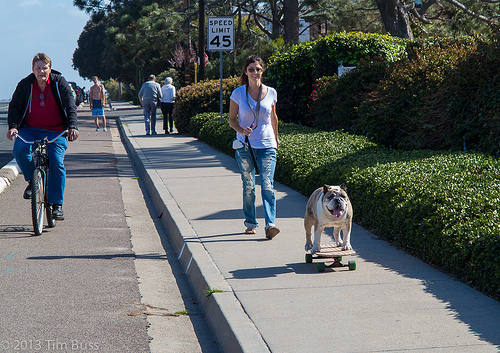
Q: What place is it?
A: It is a sidewalk.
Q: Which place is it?
A: It is a sidewalk.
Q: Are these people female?
A: No, they are both male and female.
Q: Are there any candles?
A: No, there are no candles.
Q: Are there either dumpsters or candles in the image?
A: No, there are no candles or dumpsters.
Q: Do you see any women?
A: Yes, there is a woman.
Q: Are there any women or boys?
A: Yes, there is a woman.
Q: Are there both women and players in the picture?
A: No, there is a woman but no players.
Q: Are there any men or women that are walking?
A: Yes, the woman is walking.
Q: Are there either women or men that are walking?
A: Yes, the woman is walking.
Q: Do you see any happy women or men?
A: Yes, there is a happy woman.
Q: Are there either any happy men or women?
A: Yes, there is a happy woman.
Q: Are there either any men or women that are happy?
A: Yes, the woman is happy.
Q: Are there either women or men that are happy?
A: Yes, the woman is happy.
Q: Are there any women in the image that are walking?
A: Yes, there is a woman that is walking.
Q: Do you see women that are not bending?
A: Yes, there is a woman that is walking .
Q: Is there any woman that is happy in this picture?
A: Yes, there is a happy woman.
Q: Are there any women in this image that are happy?
A: Yes, there is a happy woman.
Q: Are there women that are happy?
A: Yes, there is a woman that is happy.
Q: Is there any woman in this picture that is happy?
A: Yes, there is a woman that is happy.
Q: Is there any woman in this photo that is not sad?
A: Yes, there is a happy woman.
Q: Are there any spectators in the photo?
A: No, there are no spectators.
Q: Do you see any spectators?
A: No, there are no spectators.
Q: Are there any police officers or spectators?
A: No, there are no spectators or police officers.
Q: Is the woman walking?
A: Yes, the woman is walking.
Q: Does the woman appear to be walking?
A: Yes, the woman is walking.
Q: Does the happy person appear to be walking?
A: Yes, the woman is walking.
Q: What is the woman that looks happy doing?
A: The woman is walking.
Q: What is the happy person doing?
A: The woman is walking.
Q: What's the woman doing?
A: The woman is walking.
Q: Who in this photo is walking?
A: The woman is walking.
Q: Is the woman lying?
A: No, the woman is walking.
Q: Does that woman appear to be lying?
A: No, the woman is walking.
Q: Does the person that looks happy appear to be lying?
A: No, the woman is walking.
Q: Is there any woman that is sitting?
A: No, there is a woman but she is walking.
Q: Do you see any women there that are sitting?
A: No, there is a woman but she is walking.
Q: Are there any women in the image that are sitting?
A: No, there is a woman but she is walking.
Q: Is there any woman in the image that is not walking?
A: No, there is a woman but she is walking.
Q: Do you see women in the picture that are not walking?
A: No, there is a woman but she is walking.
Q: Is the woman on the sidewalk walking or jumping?
A: The woman is walking.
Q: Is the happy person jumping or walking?
A: The woman is walking.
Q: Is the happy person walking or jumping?
A: The woman is walking.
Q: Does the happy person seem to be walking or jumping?
A: The woman is walking.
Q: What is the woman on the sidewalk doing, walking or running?
A: The woman is walking.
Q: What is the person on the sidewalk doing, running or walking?
A: The woman is walking.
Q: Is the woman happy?
A: Yes, the woman is happy.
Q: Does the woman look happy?
A: Yes, the woman is happy.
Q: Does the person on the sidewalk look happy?
A: Yes, the woman is happy.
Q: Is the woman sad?
A: No, the woman is happy.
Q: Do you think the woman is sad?
A: No, the woman is happy.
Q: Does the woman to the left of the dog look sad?
A: No, the woman is happy.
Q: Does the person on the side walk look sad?
A: No, the woman is happy.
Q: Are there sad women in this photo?
A: No, there is a woman but she is happy.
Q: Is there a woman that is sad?
A: No, there is a woman but she is happy.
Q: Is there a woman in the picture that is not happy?
A: No, there is a woman but she is happy.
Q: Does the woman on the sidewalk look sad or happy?
A: The woman is happy.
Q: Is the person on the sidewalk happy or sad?
A: The woman is happy.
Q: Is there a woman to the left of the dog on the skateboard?
A: Yes, there is a woman to the left of the dog.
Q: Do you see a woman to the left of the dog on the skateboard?
A: Yes, there is a woman to the left of the dog.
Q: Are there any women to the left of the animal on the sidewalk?
A: Yes, there is a woman to the left of the dog.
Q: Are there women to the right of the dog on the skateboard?
A: No, the woman is to the left of the dog.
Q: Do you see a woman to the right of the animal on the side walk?
A: No, the woman is to the left of the dog.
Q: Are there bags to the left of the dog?
A: No, there is a woman to the left of the dog.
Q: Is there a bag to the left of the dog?
A: No, there is a woman to the left of the dog.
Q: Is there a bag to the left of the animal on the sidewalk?
A: No, there is a woman to the left of the dog.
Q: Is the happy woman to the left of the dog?
A: Yes, the woman is to the left of the dog.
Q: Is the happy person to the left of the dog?
A: Yes, the woman is to the left of the dog.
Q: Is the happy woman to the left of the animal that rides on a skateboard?
A: Yes, the woman is to the left of the dog.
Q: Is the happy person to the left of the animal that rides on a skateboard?
A: Yes, the woman is to the left of the dog.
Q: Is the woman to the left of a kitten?
A: No, the woman is to the left of the dog.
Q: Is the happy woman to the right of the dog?
A: No, the woman is to the left of the dog.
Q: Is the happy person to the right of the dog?
A: No, the woman is to the left of the dog.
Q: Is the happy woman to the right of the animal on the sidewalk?
A: No, the woman is to the left of the dog.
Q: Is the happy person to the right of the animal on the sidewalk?
A: No, the woman is to the left of the dog.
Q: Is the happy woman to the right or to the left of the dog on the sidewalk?
A: The woman is to the left of the dog.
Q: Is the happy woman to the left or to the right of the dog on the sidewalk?
A: The woman is to the left of the dog.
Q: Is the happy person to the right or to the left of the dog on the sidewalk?
A: The woman is to the left of the dog.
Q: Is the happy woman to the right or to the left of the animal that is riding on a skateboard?
A: The woman is to the left of the dog.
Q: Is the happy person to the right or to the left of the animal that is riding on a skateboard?
A: The woman is to the left of the dog.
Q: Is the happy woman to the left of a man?
A: No, the woman is to the right of a man.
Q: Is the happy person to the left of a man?
A: No, the woman is to the right of a man.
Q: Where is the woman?
A: The woman is on the sidewalk.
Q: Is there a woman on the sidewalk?
A: Yes, there is a woman on the sidewalk.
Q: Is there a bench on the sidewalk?
A: No, there is a woman on the sidewalk.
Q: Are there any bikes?
A: Yes, there is a bike.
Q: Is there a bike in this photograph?
A: Yes, there is a bike.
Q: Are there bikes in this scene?
A: Yes, there is a bike.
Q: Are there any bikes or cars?
A: Yes, there is a bike.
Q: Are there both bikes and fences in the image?
A: No, there is a bike but no fences.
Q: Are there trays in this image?
A: No, there are no trays.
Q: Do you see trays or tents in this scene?
A: No, there are no trays or tents.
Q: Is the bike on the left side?
A: Yes, the bike is on the left of the image.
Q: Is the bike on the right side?
A: No, the bike is on the left of the image.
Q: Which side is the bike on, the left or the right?
A: The bike is on the left of the image.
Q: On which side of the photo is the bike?
A: The bike is on the left of the image.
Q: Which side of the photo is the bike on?
A: The bike is on the left of the image.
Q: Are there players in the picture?
A: No, there are no players.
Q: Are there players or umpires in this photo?
A: No, there are no players or umpires.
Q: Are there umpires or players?
A: No, there are no players or umpires.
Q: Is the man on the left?
A: Yes, the man is on the left of the image.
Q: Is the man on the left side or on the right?
A: The man is on the left of the image.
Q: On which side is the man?
A: The man is on the left of the image.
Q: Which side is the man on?
A: The man is on the left of the image.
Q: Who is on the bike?
A: The man is on the bike.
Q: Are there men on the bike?
A: Yes, there is a man on the bike.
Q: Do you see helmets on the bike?
A: No, there is a man on the bike.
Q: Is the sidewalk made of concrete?
A: Yes, the sidewalk is made of concrete.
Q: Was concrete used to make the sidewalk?
A: Yes, the sidewalk is made of concrete.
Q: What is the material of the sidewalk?
A: The sidewalk is made of cement.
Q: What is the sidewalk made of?
A: The sidewalk is made of concrete.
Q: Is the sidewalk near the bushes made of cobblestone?
A: No, the side walk is made of concrete.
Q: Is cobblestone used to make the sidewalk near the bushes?
A: No, the side walk is made of concrete.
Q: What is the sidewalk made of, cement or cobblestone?
A: The sidewalk is made of cement.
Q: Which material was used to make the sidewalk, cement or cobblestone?
A: The sidewalk is made of cement.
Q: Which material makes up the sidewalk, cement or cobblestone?
A: The sidewalk is made of cement.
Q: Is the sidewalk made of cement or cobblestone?
A: The sidewalk is made of cement.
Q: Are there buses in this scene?
A: No, there are no buses.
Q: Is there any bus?
A: No, there are no buses.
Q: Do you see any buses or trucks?
A: No, there are no buses or trucks.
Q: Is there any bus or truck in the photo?
A: No, there are no buses or trucks.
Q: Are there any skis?
A: No, there are no skis.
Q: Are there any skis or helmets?
A: No, there are no skis or helmets.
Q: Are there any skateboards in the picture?
A: Yes, there is a skateboard.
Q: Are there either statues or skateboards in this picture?
A: Yes, there is a skateboard.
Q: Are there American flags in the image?
A: No, there are no American flags.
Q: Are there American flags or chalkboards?
A: No, there are no American flags or chalkboards.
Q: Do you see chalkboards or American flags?
A: No, there are no American flags or chalkboards.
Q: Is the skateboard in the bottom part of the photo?
A: Yes, the skateboard is in the bottom of the image.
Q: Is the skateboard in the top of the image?
A: No, the skateboard is in the bottom of the image.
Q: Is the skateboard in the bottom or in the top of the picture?
A: The skateboard is in the bottom of the image.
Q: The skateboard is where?
A: The skateboard is on the sidewalk.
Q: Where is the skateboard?
A: The skateboard is on the sidewalk.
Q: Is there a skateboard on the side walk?
A: Yes, there is a skateboard on the side walk.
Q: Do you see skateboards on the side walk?
A: Yes, there is a skateboard on the side walk.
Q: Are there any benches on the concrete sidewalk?
A: No, there is a skateboard on the sidewalk.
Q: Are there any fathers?
A: No, there are no fathers.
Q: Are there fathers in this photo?
A: No, there are no fathers.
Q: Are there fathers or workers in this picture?
A: No, there are no fathers or workers.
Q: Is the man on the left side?
A: Yes, the man is on the left of the image.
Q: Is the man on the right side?
A: No, the man is on the left of the image.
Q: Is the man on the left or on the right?
A: The man is on the left of the image.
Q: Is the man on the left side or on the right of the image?
A: The man is on the left of the image.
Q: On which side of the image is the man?
A: The man is on the left of the image.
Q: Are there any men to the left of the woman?
A: Yes, there is a man to the left of the woman.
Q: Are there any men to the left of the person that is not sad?
A: Yes, there is a man to the left of the woman.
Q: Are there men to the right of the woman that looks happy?
A: No, the man is to the left of the woman.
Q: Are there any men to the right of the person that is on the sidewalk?
A: No, the man is to the left of the woman.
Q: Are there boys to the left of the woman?
A: No, there is a man to the left of the woman.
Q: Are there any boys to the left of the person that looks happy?
A: No, there is a man to the left of the woman.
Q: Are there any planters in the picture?
A: No, there are no planters.